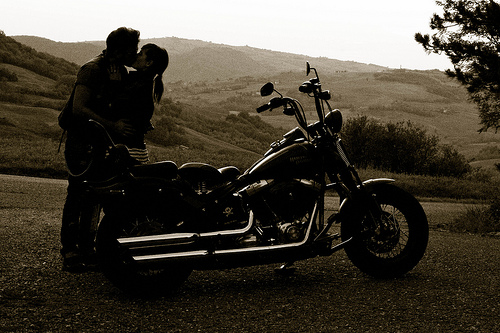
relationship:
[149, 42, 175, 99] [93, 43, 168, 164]
pony tail belongs to she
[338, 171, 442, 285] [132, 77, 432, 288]
front tire of motorcycle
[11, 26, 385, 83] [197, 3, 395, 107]
mountain range in distance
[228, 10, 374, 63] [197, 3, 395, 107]
sky in distance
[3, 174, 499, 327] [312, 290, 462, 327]
gravel on ground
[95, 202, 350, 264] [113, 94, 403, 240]
two mufflers of motorcycle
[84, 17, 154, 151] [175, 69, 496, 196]
they are in hills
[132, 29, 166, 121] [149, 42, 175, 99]
she wearing pony tail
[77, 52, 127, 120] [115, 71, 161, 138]
he wearing jacket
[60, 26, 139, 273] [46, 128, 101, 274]
he wearing wearing jeans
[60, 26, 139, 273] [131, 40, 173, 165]
he a woman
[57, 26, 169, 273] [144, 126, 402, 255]
couple embracing next to motorcycle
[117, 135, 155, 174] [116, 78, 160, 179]
tail of shirt